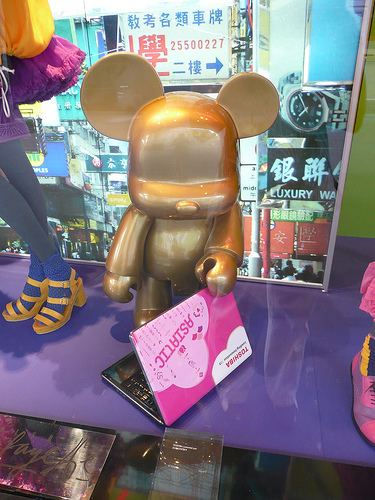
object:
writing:
[265, 151, 331, 186]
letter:
[184, 315, 193, 328]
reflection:
[237, 279, 322, 414]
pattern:
[52, 262, 69, 275]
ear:
[77, 51, 163, 142]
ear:
[215, 74, 280, 139]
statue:
[79, 51, 279, 337]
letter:
[126, 279, 256, 429]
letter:
[228, 357, 233, 365]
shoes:
[3, 269, 49, 323]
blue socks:
[40, 253, 78, 331]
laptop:
[99, 283, 255, 425]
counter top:
[8, 236, 372, 460]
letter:
[149, 352, 167, 370]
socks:
[0, 247, 45, 318]